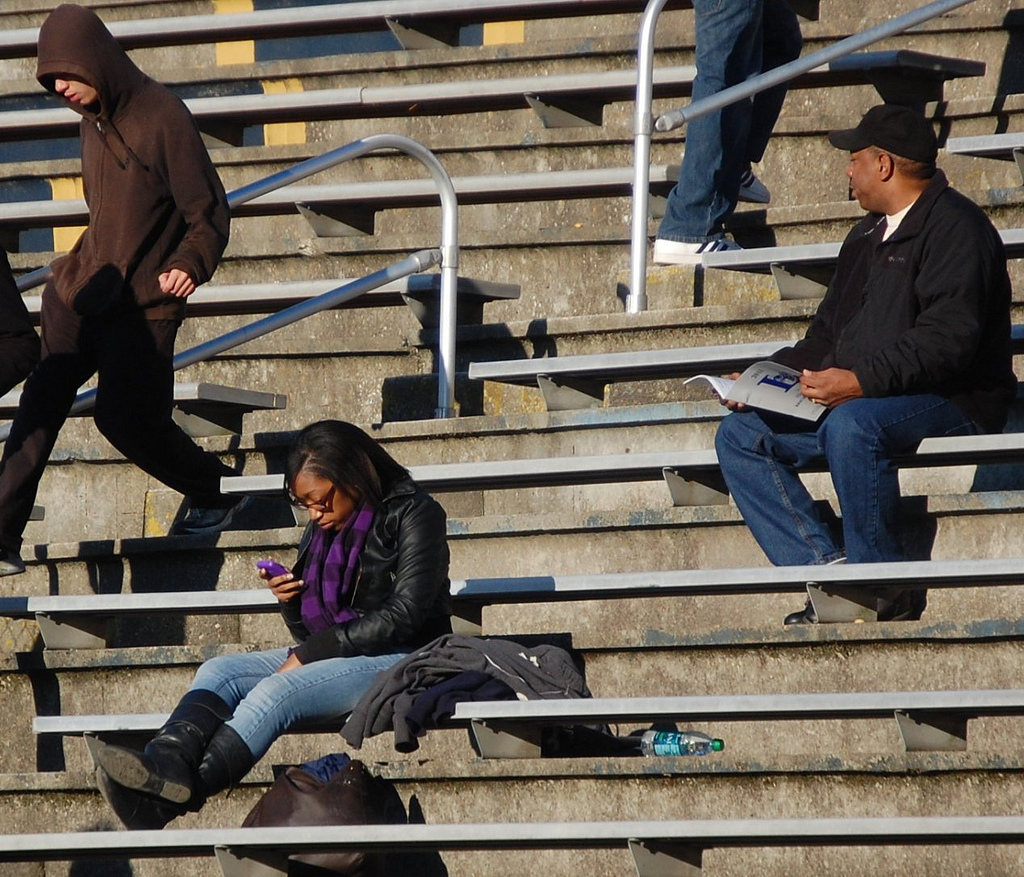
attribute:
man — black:
[678, 250, 842, 519]